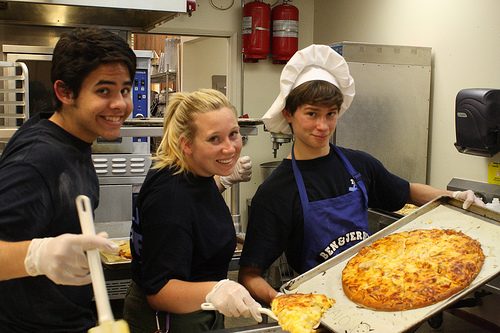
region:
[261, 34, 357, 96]
white hat on the boy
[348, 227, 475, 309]
a large pizza on tray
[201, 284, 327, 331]
girl holding a piece of pizza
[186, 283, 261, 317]
person wearing a plastic glove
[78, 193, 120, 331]
young boy holding a spoon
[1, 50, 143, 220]
boy is smiling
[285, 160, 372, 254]
blue apron being worn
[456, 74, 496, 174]
dispenser is hanging on wall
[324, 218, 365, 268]
logo of company on apron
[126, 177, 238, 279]
woman wearing a black shirt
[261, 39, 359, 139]
A white chef's hat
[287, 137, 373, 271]
A blue colored apron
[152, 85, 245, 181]
Blonde hair on woman's head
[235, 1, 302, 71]
Two red fire hydrants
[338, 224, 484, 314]
A round pizza pie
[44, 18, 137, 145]
Young man is smiling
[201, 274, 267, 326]
A white plastic glove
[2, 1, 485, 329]
Young people in a kitchen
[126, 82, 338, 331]
Young woman holding a slice of pizza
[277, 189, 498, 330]
Pizza on a baking tray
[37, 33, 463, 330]
three teenagers making pizza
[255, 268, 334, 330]
slice of pizza on spatula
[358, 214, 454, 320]
round pizza on metal pan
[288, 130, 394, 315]
blue apron on cook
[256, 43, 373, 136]
white cook's hat on boy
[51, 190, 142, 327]
plastic spatula in hand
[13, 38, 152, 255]
large oven in the background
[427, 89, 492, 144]
soap dispenser on wall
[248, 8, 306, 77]
fire extinguishers on wall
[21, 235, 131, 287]
white latex glove on hand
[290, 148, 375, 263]
A blue chef coat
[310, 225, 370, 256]
The words 'BEN&JEREY' in white writing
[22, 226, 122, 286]
A white rubber glove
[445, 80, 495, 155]
A paper towel dispenser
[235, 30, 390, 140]
A white chef toque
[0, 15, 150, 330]
A man with a dirty shirt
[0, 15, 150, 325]
A man holding a white scraper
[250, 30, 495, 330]
A man holding a tray of pizza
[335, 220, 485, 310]
A very crispy looking pizza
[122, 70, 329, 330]
A woman holding a pizza on a spatula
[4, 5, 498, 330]
three employees enjoying a freshly baked pizza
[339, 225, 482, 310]
freshly baked cheese pizza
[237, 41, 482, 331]
pizza maker wearing poofy chef hat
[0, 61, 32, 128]
metal speed rack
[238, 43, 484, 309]
young man wearing chef hat, blue tshirt and blue Ben & Jerry's apron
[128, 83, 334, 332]
food service worker holding slice of cheese pizza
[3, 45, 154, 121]
commercial oven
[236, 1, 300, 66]
fire suppression equipment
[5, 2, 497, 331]
commercial food preparation area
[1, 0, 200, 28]
hood system component